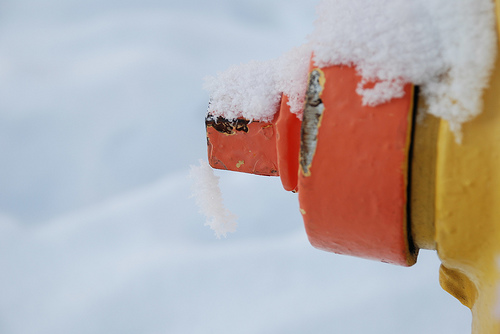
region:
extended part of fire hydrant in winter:
[6, 3, 495, 328]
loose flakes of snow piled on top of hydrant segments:
[206, 5, 499, 260]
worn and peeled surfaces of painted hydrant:
[201, 54, 327, 181]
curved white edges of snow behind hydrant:
[8, 8, 476, 332]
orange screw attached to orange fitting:
[201, 55, 421, 270]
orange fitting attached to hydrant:
[291, 40, 497, 330]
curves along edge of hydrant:
[416, 225, 483, 330]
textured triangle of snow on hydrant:
[351, 10, 450, 88]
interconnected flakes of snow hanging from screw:
[178, 118, 245, 245]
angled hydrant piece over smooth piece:
[201, 53, 411, 265]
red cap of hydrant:
[185, 46, 415, 244]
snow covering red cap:
[199, 23, 399, 100]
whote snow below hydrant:
[15, 34, 412, 332]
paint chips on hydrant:
[295, 81, 327, 170]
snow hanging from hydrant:
[181, 152, 237, 251]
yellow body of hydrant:
[413, 76, 498, 276]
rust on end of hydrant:
[195, 117, 252, 132]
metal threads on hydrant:
[406, 94, 412, 248]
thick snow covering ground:
[27, 9, 283, 318]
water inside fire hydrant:
[408, 113, 498, 295]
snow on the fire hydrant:
[196, 8, 498, 319]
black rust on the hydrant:
[198, 110, 254, 137]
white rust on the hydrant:
[307, 63, 320, 178]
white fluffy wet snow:
[353, 13, 428, 58]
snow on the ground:
[105, 177, 164, 257]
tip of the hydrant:
[195, 52, 301, 188]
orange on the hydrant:
[323, 146, 391, 204]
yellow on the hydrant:
[453, 161, 477, 251]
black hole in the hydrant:
[405, 126, 412, 176]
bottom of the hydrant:
[455, 308, 496, 333]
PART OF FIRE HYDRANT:
[202, 73, 298, 182]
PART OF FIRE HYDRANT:
[311, 68, 387, 120]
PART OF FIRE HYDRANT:
[319, 128, 376, 154]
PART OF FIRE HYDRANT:
[333, 166, 386, 192]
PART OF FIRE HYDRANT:
[306, 209, 344, 233]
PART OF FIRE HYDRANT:
[351, 232, 397, 257]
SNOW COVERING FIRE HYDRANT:
[345, 25, 406, 61]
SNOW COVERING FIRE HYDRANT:
[439, 8, 477, 65]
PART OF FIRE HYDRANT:
[417, 120, 435, 168]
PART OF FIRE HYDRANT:
[449, 185, 487, 248]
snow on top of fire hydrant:
[198, 1, 490, 122]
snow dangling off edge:
[185, 159, 240, 239]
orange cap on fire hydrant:
[201, 23, 421, 271]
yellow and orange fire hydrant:
[197, 0, 497, 333]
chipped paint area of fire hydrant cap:
[300, 61, 328, 176]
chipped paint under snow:
[202, 98, 258, 143]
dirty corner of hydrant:
[437, 260, 477, 305]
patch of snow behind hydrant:
[10, 23, 190, 240]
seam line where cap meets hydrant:
[405, 75, 422, 269]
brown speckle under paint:
[306, 83, 323, 115]